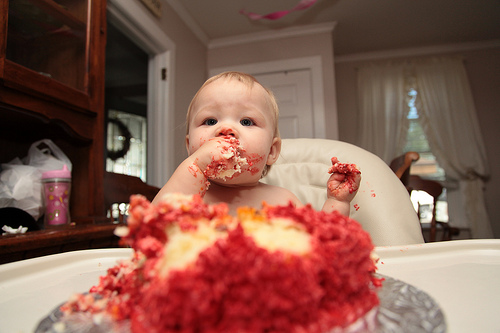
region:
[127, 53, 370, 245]
baby is eating cake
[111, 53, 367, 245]
the baby is blonde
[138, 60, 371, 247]
right hand of baby on mouth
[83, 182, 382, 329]
cake is covered with red frosting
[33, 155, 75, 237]
a pink bottle of baby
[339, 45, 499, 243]
white curtains on window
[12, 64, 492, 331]
baby is in high chair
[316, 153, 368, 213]
hand has red frosting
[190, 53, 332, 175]
white door behind baby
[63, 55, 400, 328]
cake in front baby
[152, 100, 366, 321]
a kid in a high chair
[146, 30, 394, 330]
a baby sitting in a high chair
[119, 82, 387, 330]
a child eating in a high chair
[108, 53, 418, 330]
a baby eatting in a high chair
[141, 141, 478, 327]
a cake on the high chair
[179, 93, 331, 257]
a baby with cake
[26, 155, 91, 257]
a pink sippy cup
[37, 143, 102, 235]
a pink sippy cup on table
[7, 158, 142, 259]
a pink sippy cup inside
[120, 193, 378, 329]
yellow cake decorated with red frosting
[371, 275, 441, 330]
one side of a cut glass cake platter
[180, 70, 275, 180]
a baby enjoys her cake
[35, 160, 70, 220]
a pink sippy cup on a china cabinet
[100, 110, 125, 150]
a wearth hangs on the front door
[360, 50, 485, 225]
white ruffled curtains pulled back in the front window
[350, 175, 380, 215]
frosting on the seat of the high chair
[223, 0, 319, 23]
two toned pink streamer on ceiling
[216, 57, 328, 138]
a white closet door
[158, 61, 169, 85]
an old hinge on the door frame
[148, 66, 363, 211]
a baby eating some cake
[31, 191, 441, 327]
the cake the baby is eating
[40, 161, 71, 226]
a pink cup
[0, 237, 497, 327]
white tray the cake is on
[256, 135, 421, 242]
part of the baby's high chair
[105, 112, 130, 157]
a wreath on a door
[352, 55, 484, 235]
white window curtains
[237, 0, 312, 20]
part of a pink ribbon on the ceiling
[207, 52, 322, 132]
white closed door behind the baby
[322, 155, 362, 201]
cake covered hand of the baby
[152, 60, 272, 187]
baby is eating cake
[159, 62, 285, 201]
baby is eating cake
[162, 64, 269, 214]
baby is eating cake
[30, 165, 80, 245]
the tumbler is pink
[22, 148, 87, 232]
the tumbler is pink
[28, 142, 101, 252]
the tumbler is pink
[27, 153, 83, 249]
the tumbler is pink